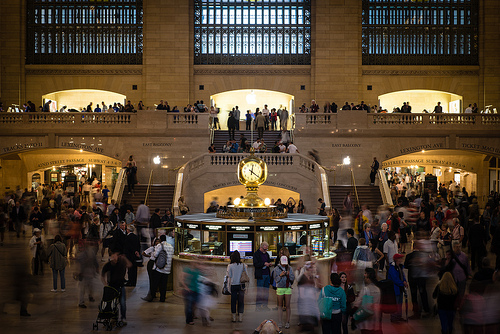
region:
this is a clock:
[231, 157, 266, 189]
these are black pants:
[149, 264, 176, 306]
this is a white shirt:
[217, 260, 256, 292]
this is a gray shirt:
[274, 262, 297, 289]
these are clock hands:
[250, 160, 265, 184]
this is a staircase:
[110, 155, 195, 226]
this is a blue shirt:
[316, 283, 349, 318]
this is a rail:
[325, 153, 385, 235]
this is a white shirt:
[149, 237, 184, 282]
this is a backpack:
[150, 237, 170, 279]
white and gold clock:
[238, 153, 268, 208]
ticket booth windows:
[178, 216, 335, 262]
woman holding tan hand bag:
[225, 249, 250, 316]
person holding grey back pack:
[151, 234, 173, 294]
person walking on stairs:
[123, 154, 138, 194]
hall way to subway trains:
[33, 154, 119, 204]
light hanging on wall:
[153, 155, 161, 162]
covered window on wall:
[193, 3, 312, 61]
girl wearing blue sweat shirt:
[321, 274, 348, 324]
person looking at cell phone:
[274, 253, 295, 310]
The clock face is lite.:
[232, 155, 271, 187]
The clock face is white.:
[231, 155, 273, 186]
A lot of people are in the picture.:
[338, 175, 492, 320]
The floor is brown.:
[142, 310, 185, 331]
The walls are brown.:
[147, 0, 195, 150]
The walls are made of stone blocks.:
[148, 7, 188, 104]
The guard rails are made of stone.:
[4, 110, 209, 132]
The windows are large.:
[24, 0, 489, 72]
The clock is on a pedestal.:
[232, 150, 274, 213]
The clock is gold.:
[229, 153, 275, 221]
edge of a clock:
[233, 150, 253, 175]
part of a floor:
[134, 295, 169, 327]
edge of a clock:
[260, 159, 270, 184]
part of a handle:
[319, 173, 334, 201]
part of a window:
[242, 23, 290, 58]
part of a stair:
[356, 177, 368, 192]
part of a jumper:
[332, 295, 347, 310]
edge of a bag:
[236, 262, 246, 277]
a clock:
[228, 158, 301, 223]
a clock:
[190, 81, 375, 241]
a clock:
[220, 105, 307, 253]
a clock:
[158, 88, 328, 325]